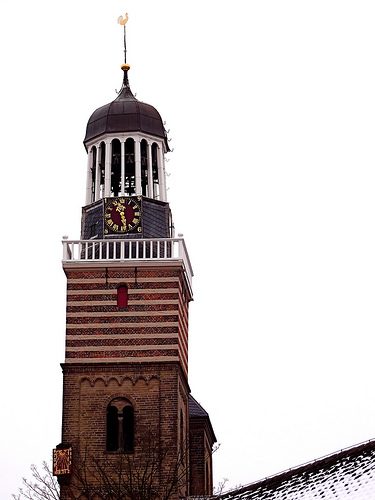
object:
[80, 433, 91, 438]
brick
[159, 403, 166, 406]
brick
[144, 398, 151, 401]
brick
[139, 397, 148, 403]
brick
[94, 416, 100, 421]
brick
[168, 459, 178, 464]
brick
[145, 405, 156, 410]
brick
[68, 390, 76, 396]
brick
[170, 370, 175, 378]
brick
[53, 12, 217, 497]
tower